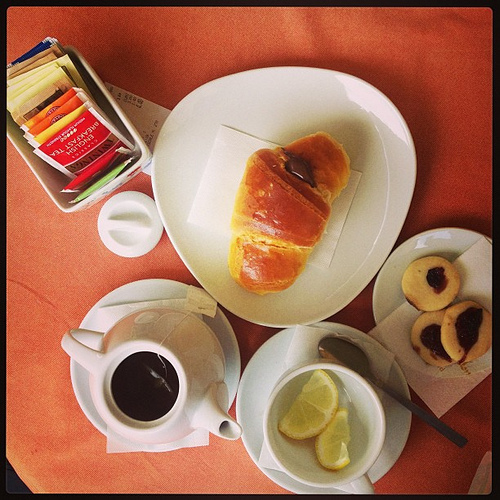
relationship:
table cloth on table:
[427, 17, 476, 177] [7, 6, 486, 253]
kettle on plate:
[61, 306, 243, 443] [67, 275, 242, 452]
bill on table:
[99, 78, 172, 177] [0, 22, 482, 492]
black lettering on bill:
[116, 91, 145, 108] [99, 78, 172, 177]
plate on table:
[151, 64, 420, 330] [0, 22, 482, 492]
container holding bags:
[4, 39, 151, 212] [4, 40, 138, 204]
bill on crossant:
[99, 78, 172, 177] [226, 130, 351, 295]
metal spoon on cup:
[316, 333, 470, 450] [264, 357, 388, 498]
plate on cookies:
[371, 227, 491, 375] [396, 258, 490, 368]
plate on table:
[146, 32, 438, 367] [0, 22, 482, 492]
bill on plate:
[99, 78, 172, 177] [145, 62, 435, 340]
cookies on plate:
[400, 254, 493, 371] [371, 227, 491, 375]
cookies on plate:
[400, 254, 493, 371] [371, 227, 491, 380]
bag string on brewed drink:
[156, 283, 218, 349] [109, 355, 180, 418]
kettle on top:
[63, 304, 249, 458] [93, 187, 163, 260]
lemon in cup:
[277, 368, 351, 470] [259, 362, 390, 487]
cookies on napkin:
[396, 248, 493, 373] [94, 296, 221, 457]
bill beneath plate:
[103, 80, 176, 177] [151, 64, 420, 330]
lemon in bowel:
[270, 334, 375, 500] [262, 362, 386, 490]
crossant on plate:
[214, 109, 359, 301] [129, 85, 422, 350]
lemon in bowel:
[277, 368, 351, 470] [267, 361, 384, 488]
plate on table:
[371, 227, 491, 375] [0, 22, 482, 492]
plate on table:
[235, 322, 410, 492] [0, 22, 482, 492]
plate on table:
[69, 278, 241, 438] [0, 22, 482, 492]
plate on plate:
[371, 227, 491, 380] [235, 322, 412, 494]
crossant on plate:
[226, 130, 351, 295] [151, 64, 420, 330]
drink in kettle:
[110, 350, 177, 422] [56, 290, 241, 490]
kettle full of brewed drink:
[61, 306, 243, 443] [108, 349, 182, 424]